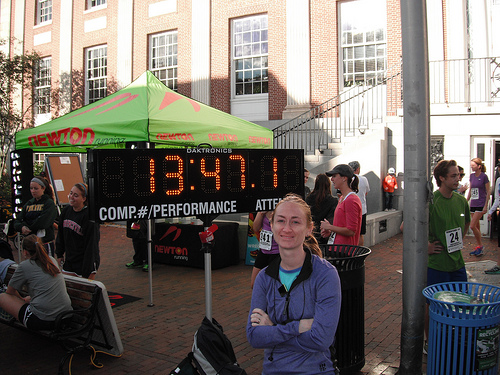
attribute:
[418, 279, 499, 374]
trash — blue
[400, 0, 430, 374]
pole — grey, metalic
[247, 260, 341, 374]
sweater — blue, purple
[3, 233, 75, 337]
lady — smiling, posing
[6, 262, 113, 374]
bench — wooden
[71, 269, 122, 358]
table — leaning, white, written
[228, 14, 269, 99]
window — closed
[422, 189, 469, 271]
shirt — green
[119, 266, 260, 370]
sidewalk — bricks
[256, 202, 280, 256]
shirt — purple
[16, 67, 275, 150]
umbrella — green, written, green\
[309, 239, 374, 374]
trashbiln — black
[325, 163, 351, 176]
cap — colored, nice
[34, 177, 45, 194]
headband — grey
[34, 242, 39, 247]
hairtie — white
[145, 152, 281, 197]
time — then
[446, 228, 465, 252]
tag — number 24, racer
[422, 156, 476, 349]
man — racer, standing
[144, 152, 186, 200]
digits — some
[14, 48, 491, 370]
street — busy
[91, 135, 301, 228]
clock — digital